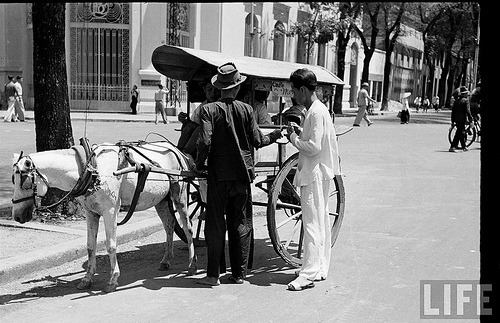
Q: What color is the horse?
A: White.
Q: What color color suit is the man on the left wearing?
A: Black.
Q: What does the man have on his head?
A: Hat.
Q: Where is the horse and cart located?
A: Street.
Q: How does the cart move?
A: Horse.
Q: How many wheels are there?
A: Two.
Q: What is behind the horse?
A: Tree.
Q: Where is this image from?
A: Life magazine.